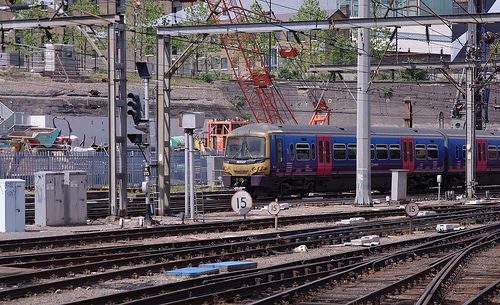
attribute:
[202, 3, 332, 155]
vehicle — red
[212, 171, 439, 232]
signs — circular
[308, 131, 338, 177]
doors — red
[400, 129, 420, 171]
doors — red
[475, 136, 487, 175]
doors — red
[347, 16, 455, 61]
wall — is white, is blue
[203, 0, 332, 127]
crane — is large, is red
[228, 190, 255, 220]
sign — white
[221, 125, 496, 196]
train — gray, blue, yellow, red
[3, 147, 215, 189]
fence — is is blue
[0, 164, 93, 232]
boxes — metal, gray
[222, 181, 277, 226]
sign — circular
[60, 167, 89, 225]
box — electrical wires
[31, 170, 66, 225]
box — electrical wires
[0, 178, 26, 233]
box — electrical wires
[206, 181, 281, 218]
number 15 — Large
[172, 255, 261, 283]
panels — blue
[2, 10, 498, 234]
structure — metal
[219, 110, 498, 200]
train — blue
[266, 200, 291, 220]
signs — circular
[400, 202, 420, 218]
signs — circular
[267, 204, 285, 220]
circle — Small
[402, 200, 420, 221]
circle — Small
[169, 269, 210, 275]
cover — is blue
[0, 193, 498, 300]
railroad tracks — grouped